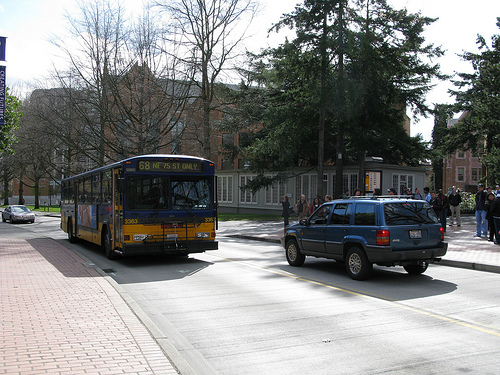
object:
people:
[279, 193, 291, 237]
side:
[451, 28, 487, 304]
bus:
[60, 152, 229, 263]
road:
[152, 270, 409, 343]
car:
[280, 196, 450, 280]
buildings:
[21, 62, 333, 199]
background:
[16, 14, 496, 146]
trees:
[255, 0, 336, 220]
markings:
[270, 289, 496, 338]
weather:
[25, 11, 262, 67]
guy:
[448, 185, 464, 227]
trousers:
[450, 205, 461, 225]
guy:
[475, 179, 492, 240]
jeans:
[475, 210, 490, 236]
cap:
[477, 182, 485, 189]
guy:
[434, 187, 449, 231]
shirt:
[435, 194, 449, 209]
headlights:
[131, 232, 149, 241]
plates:
[409, 229, 423, 239]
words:
[152, 159, 159, 169]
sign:
[78, 204, 98, 230]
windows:
[236, 173, 260, 206]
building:
[221, 156, 434, 212]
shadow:
[276, 262, 459, 303]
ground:
[201, 264, 355, 306]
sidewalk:
[15, 248, 102, 375]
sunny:
[34, 3, 262, 43]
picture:
[0, 0, 499, 375]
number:
[138, 160, 145, 171]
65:
[134, 155, 152, 174]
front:
[123, 160, 212, 253]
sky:
[16, 8, 266, 38]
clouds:
[20, 12, 49, 40]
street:
[206, 282, 500, 339]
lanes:
[260, 262, 458, 349]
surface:
[174, 301, 487, 361]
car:
[2, 204, 35, 223]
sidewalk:
[448, 218, 499, 272]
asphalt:
[135, 253, 278, 299]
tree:
[76, 1, 122, 208]